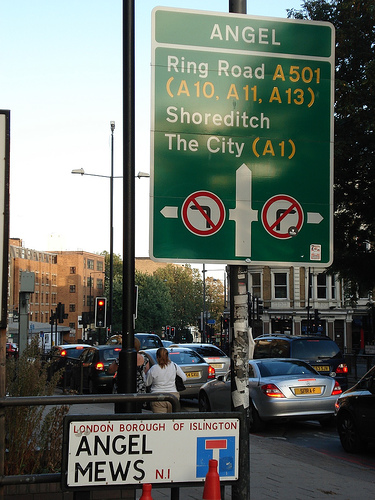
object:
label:
[150, 5, 335, 268]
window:
[271, 269, 291, 300]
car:
[335, 365, 375, 453]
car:
[138, 348, 215, 409]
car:
[33, 343, 93, 387]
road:
[40, 346, 375, 499]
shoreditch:
[165, 106, 269, 129]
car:
[198, 357, 342, 434]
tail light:
[208, 365, 216, 379]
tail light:
[335, 363, 348, 374]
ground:
[299, 448, 373, 499]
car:
[253, 333, 349, 392]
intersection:
[46, 296, 227, 348]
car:
[139, 347, 216, 395]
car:
[168, 343, 231, 381]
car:
[69, 344, 119, 394]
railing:
[0, 393, 180, 407]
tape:
[231, 294, 250, 410]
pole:
[224, 264, 249, 499]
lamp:
[71, 121, 151, 342]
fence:
[0, 392, 180, 499]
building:
[236, 265, 374, 356]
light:
[260, 383, 286, 398]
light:
[94, 362, 104, 371]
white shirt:
[140, 361, 187, 394]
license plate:
[294, 387, 321, 395]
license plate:
[311, 365, 330, 372]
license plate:
[184, 371, 199, 378]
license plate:
[208, 364, 222, 369]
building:
[6, 238, 191, 344]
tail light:
[331, 380, 342, 395]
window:
[87, 259, 94, 270]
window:
[97, 260, 103, 270]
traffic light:
[95, 296, 107, 328]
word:
[210, 24, 281, 46]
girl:
[142, 347, 186, 413]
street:
[30, 336, 374, 495]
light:
[332, 380, 343, 396]